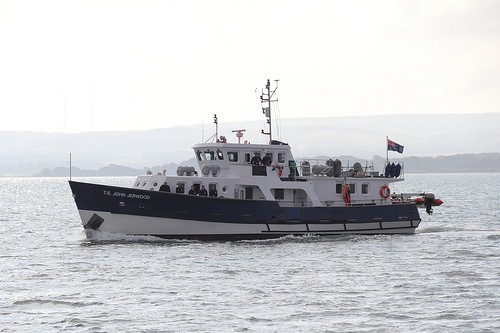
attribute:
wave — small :
[9, 292, 104, 314]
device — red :
[373, 179, 403, 202]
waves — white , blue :
[378, 261, 473, 321]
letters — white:
[103, 189, 150, 199]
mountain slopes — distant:
[2, 101, 497, 178]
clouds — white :
[23, 37, 123, 89]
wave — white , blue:
[225, 269, 306, 310]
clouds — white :
[1, 14, 498, 132]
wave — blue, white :
[15, 290, 102, 312]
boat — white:
[64, 67, 452, 245]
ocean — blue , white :
[18, 222, 495, 314]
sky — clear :
[1, 1, 498, 141]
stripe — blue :
[158, 195, 262, 222]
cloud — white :
[62, 39, 232, 89]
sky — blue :
[1, 0, 499, 128]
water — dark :
[0, 171, 499, 332]